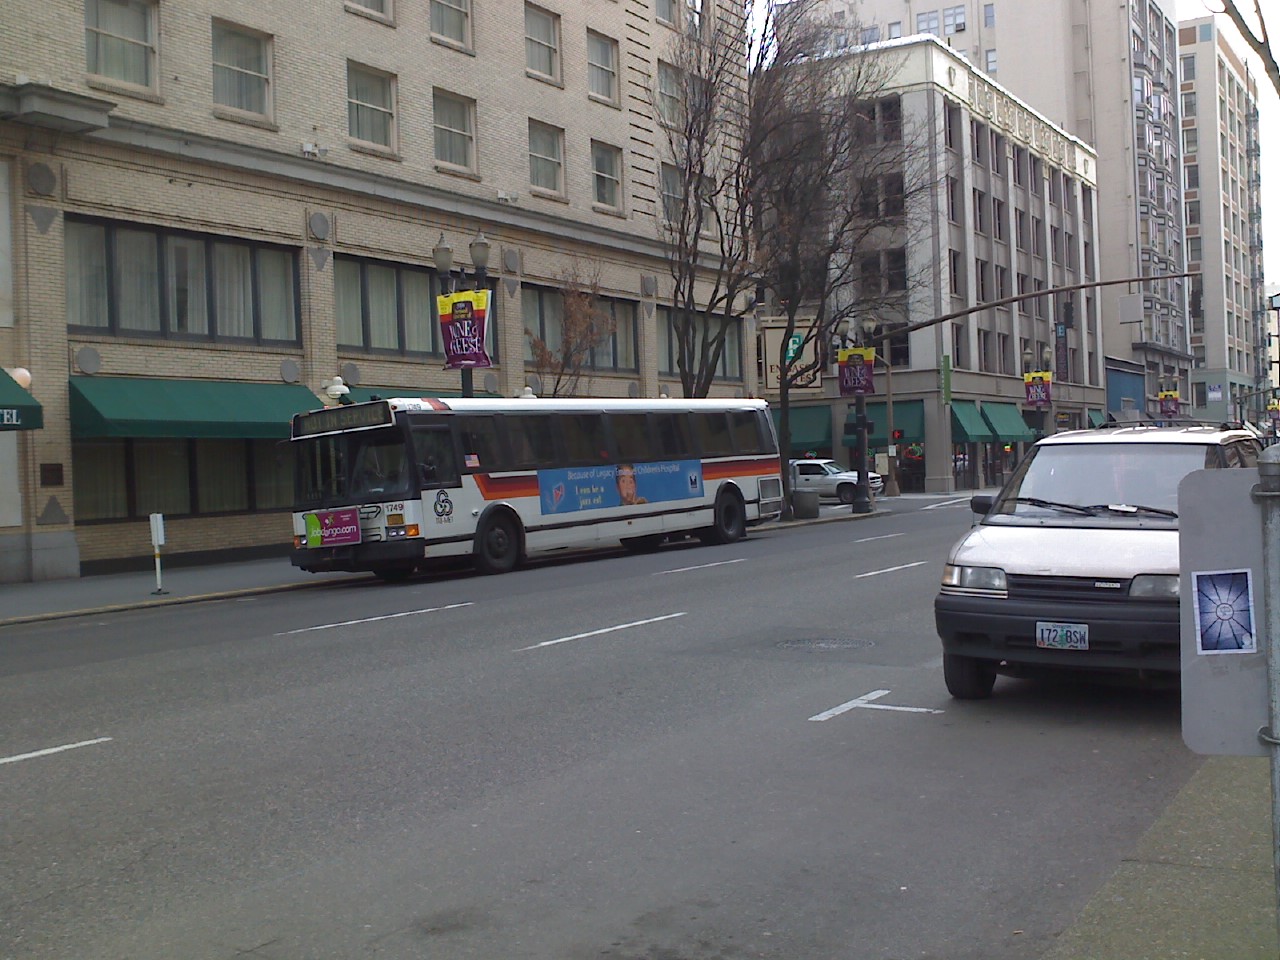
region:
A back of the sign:
[1149, 455, 1275, 760]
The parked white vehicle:
[899, 397, 1277, 753]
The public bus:
[242, 393, 810, 566]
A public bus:
[266, 382, 838, 579]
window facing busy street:
[873, 92, 900, 143]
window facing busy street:
[845, 95, 881, 150]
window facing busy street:
[877, 169, 902, 216]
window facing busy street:
[854, 246, 884, 301]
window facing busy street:
[875, 238, 909, 298]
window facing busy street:
[944, 94, 954, 149]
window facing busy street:
[946, 173, 961, 228]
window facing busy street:
[951, 319, 968, 372]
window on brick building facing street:
[88, 0, 163, 101]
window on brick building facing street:
[208, 14, 268, 117]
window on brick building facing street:
[346, 50, 397, 148]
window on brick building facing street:
[432, 86, 475, 169]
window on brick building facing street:
[529, 114, 569, 195]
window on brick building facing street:
[591, 125, 625, 211]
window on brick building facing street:
[424, 1, 475, 52]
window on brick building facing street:
[525, 0, 565, 90]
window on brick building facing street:
[589, 27, 625, 115]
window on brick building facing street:
[342, 0, 400, 25]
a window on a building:
[69, 210, 116, 361]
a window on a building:
[111, 223, 164, 325]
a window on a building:
[173, 215, 211, 337]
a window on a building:
[208, 226, 259, 350]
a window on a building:
[256, 239, 296, 354]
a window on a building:
[327, 250, 361, 376]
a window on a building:
[325, 243, 354, 352]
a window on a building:
[577, 296, 617, 376]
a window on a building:
[612, 305, 643, 369]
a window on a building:
[870, 95, 917, 159]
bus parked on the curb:
[291, 382, 812, 559]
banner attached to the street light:
[423, 289, 497, 373]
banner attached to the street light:
[840, 340, 882, 404]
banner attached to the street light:
[1010, 351, 1053, 418]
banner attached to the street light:
[1140, 390, 1185, 424]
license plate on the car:
[1035, 611, 1095, 653]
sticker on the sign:
[1185, 565, 1259, 676]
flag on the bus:
[450, 439, 486, 475]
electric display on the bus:
[288, 401, 392, 433]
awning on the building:
[64, 353, 329, 473]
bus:
[287, 346, 806, 565]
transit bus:
[295, 381, 814, 593]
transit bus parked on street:
[251, 364, 810, 563]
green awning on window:
[73, 364, 321, 448]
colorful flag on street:
[412, 251, 532, 382]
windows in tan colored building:
[90, 205, 307, 351]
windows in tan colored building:
[327, 46, 409, 155]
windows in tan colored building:
[408, 75, 495, 181]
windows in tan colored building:
[512, 112, 586, 214]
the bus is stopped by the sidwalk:
[287, 366, 795, 589]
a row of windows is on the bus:
[396, 408, 787, 473]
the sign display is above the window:
[283, 401, 403, 443]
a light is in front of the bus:
[384, 527, 411, 541]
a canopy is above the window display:
[64, 369, 338, 445]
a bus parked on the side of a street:
[276, 364, 808, 576]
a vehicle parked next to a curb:
[930, 418, 1233, 780]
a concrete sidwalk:
[102, 530, 259, 604]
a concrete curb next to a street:
[38, 574, 323, 623]